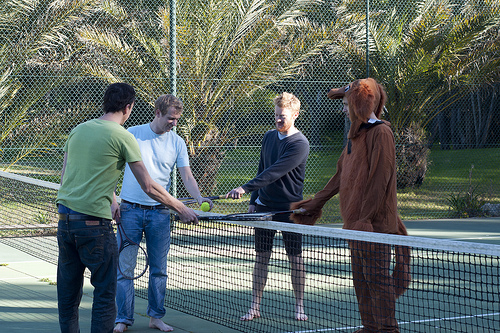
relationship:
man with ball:
[115, 94, 213, 333] [200, 201, 211, 211]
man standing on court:
[227, 92, 308, 321] [0, 217, 499, 332]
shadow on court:
[396, 288, 499, 333] [0, 217, 499, 332]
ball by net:
[200, 201, 211, 211] [0, 172, 499, 333]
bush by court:
[73, 0, 335, 197] [0, 217, 499, 332]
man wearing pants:
[115, 94, 213, 333] [115, 201, 170, 325]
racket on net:
[200, 212, 273, 221] [0, 172, 499, 333]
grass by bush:
[1, 148, 499, 237] [73, 0, 335, 197]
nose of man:
[275, 119, 280, 124] [227, 92, 308, 321]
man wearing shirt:
[55, 83, 197, 333] [54, 119, 141, 222]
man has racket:
[55, 83, 197, 333] [200, 212, 273, 221]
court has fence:
[0, 217, 499, 332] [0, 0, 499, 237]